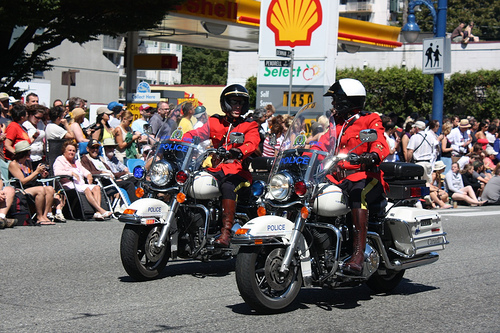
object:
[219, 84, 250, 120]
head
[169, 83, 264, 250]
person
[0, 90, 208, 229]
crowd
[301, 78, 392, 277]
policemen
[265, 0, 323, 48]
sign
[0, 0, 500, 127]
station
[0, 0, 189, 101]
tree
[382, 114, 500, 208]
people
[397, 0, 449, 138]
lamp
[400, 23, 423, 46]
light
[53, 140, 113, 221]
woman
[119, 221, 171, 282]
wheel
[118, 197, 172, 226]
fender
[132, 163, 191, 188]
headlights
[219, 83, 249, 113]
helmet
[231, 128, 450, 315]
motorcycle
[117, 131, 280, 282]
motorcycle